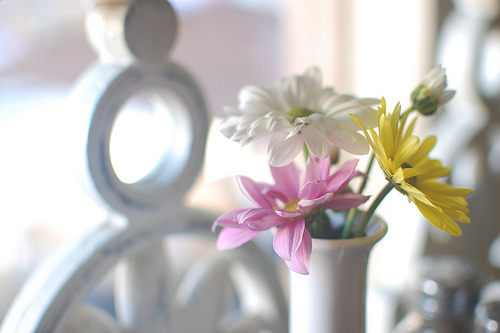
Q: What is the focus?
A: Flowers in a vase.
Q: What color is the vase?
A: White.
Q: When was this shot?
A: Daytime.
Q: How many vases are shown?
A: 1.